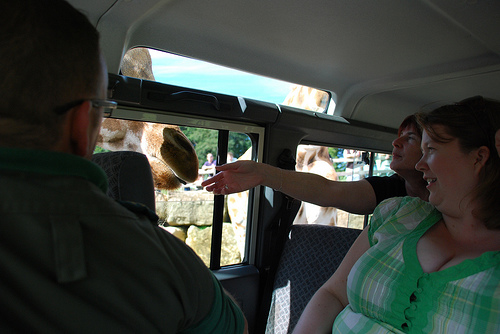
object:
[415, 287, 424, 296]
buttons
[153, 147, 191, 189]
mouth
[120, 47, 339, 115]
window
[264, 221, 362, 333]
seat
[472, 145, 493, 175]
ear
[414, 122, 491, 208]
face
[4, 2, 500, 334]
car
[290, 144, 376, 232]
window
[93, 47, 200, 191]
giraffe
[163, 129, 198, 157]
nose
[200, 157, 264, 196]
hand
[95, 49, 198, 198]
head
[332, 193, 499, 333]
shirt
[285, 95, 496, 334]
woman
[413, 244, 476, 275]
cleavage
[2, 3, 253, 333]
man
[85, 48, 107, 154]
face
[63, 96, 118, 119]
glasses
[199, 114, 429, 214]
person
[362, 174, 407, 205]
tee shirt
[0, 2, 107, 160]
hair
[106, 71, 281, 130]
handle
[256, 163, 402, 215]
arm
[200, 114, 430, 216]
woman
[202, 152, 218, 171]
person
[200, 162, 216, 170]
shirt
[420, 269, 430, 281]
buttons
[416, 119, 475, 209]
face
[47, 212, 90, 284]
loop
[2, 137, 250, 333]
shirt